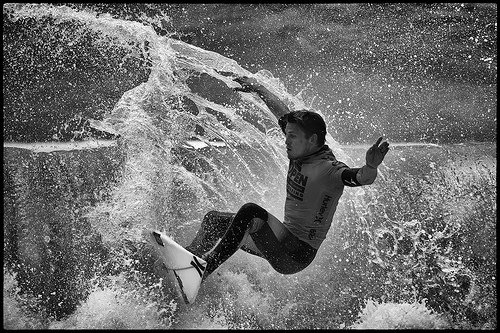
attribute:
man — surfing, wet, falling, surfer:
[186, 75, 390, 278]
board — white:
[148, 229, 209, 309]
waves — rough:
[8, 135, 278, 201]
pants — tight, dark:
[185, 201, 318, 275]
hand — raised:
[366, 136, 389, 168]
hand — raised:
[232, 75, 257, 94]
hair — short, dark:
[286, 110, 326, 148]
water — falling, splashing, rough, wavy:
[4, 6, 376, 309]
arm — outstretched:
[230, 75, 291, 135]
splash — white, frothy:
[100, 183, 152, 237]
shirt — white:
[282, 147, 347, 252]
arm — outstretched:
[337, 134, 391, 187]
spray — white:
[12, 50, 71, 107]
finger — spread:
[376, 135, 384, 148]